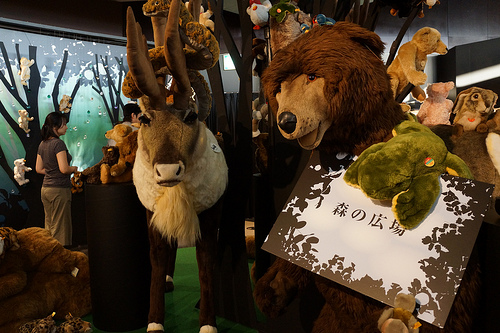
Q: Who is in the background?
A: A woman.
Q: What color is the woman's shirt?
A: Gray.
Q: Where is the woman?
A: In the rear of the exhibit.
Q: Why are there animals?
A: For decoration.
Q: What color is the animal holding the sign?
A: Green.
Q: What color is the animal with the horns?
A: Brown.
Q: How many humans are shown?
A: One.